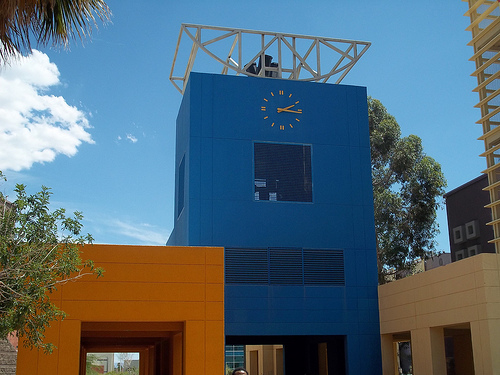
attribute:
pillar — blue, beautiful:
[172, 67, 393, 372]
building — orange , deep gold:
[11, 224, 237, 371]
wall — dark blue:
[178, 64, 403, 366]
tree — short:
[367, 91, 449, 273]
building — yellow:
[11, 238, 228, 371]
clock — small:
[256, 86, 305, 133]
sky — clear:
[0, 3, 497, 248]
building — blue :
[169, 70, 380, 373]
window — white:
[462, 220, 482, 241]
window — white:
[467, 242, 479, 257]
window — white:
[451, 222, 466, 242]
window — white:
[455, 250, 465, 260]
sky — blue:
[92, 44, 166, 121]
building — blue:
[95, 22, 497, 374]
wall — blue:
[226, 201, 376, 342]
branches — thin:
[11, 207, 101, 336]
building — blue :
[140, 18, 396, 373]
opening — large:
[215, 330, 367, 373]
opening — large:
[82, 314, 190, 372]